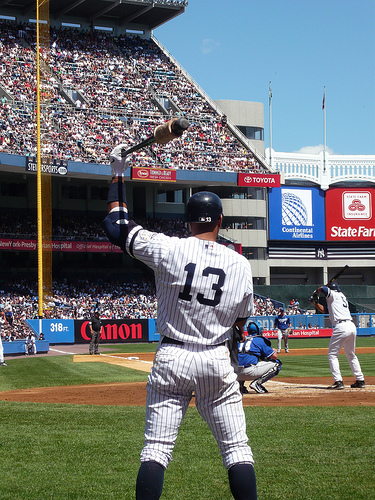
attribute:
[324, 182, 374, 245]
state farm — advertised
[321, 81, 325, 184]
pole — flag pole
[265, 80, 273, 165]
pole — flag pole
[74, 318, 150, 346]
canon — sponsor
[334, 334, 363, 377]
pants — white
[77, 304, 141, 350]
advertising — Canon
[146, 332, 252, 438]
pants — white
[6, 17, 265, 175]
group — of people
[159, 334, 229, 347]
belt — dark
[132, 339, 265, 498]
pants — pinstriped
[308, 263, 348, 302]
baseball bat — being held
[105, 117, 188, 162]
baseball bat — being held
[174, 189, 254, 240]
helmet — baseball helmet, plastic, black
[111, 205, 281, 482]
uniform — white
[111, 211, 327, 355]
uniform — white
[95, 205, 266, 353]
shirt — white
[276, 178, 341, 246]
ad — blue and white, for continental airlines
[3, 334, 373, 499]
lawn — well manicured, green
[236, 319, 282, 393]
catcher — bending down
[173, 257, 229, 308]
number — 13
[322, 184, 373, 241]
sign — red, white, for State Farm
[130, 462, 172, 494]
socks — black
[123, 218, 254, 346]
shirt — white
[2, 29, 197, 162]
audience — group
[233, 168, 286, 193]
banner — red, white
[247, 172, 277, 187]
advertisement — toyota advertisement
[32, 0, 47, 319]
pole — yellow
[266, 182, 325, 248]
sign — blue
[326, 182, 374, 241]
sign — red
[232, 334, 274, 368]
shirt — blue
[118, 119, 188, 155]
baseball bat — black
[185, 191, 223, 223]
hat — baseball hat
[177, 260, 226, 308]
13 — number